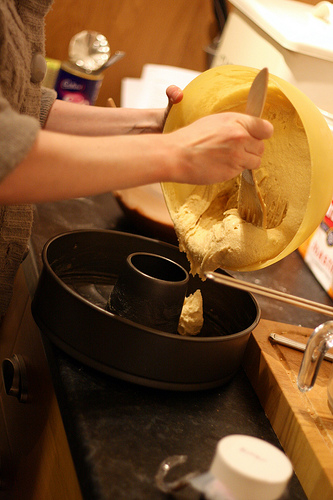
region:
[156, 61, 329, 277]
cake mixture in a yellow mixing bowl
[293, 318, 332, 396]
handle of a glass jug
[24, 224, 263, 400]
non stick cake ring tin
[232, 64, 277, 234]
wooden spatula scraping cake mix out of a bowl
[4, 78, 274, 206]
arms are held out in front of a person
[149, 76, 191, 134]
left hand grips the edge of a mixing bowl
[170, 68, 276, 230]
right hand holds a wooden spatula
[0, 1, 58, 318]
person is wearing a grey colored sweater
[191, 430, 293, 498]
a white measuring cup upside down on a granite counter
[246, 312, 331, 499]
wooden chopping board on a granite counter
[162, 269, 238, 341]
A drop of cake batter in a pan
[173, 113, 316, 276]
Cake batter being scraped into a pan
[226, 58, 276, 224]
A wooden fork in a woman's hand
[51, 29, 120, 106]
A frosting container in the background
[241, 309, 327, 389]
A wooden cutting board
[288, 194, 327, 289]
A bag of flour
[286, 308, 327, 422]
A glass measuring cup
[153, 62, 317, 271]
A yellow bowl full of cake batter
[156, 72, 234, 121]
A woman's hand gripping a yellow bowl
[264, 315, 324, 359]
A knife resting on a cutting board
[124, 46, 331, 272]
a bowl of cake batter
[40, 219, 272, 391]
a bundt cake pan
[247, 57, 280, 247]
a wooden spoon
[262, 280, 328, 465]
a cutting board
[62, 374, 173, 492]
a black counter top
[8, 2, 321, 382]
a kitchen where someone is baking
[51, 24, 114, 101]
can of baking powder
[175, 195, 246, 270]
yellow batter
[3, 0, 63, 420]
woman wearing a sweater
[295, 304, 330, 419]
handle of a measuring cup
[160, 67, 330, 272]
yellow cake batter in a bowl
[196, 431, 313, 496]
white measuring cup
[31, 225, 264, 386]
bunt cake pan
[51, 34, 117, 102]
container of frosting with spoon in it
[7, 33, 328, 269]
woman holding bowl of cake batter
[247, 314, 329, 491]
wooden cutting board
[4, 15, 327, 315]
woman pouring cake batter into bunt pan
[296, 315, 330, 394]
glass measuring cup handle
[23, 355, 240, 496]
black kitchen counter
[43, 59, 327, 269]
woman holding a bowl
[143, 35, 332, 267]
yellow mixing bowl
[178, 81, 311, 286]
yellow cake batter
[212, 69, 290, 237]
wooden spoon used to mix batter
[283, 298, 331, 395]
handle of a glass measuring cup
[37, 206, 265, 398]
black cake pan for making bundt cakes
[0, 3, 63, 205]
person wearing gray sweater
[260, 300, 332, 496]
wooden cutting block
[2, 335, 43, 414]
brushed steel drawer pull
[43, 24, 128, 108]
container for frosting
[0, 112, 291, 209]
right arm and hand scooping batter